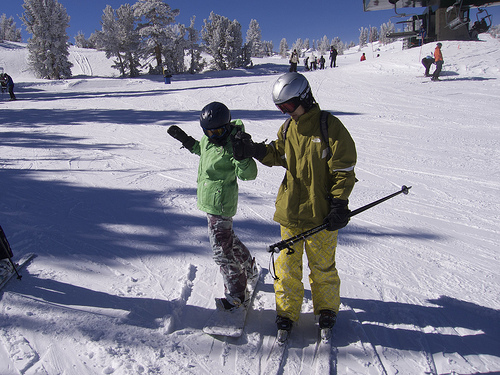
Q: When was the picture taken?
A: Daytime.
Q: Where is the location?
A: Ski resort.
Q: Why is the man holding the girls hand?
A: Help her up.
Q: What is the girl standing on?
A: Snowboard.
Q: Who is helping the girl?
A: The man.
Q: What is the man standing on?
A: Skis.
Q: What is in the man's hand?
A: Ski poles.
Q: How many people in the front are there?
A: Two.